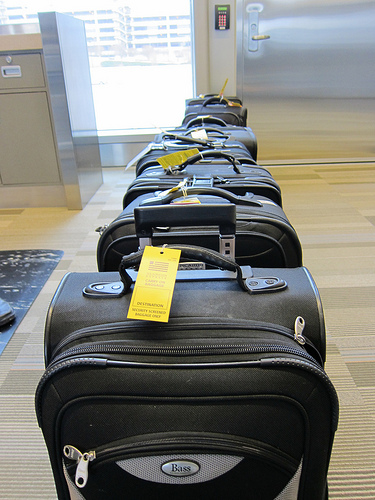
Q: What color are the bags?
A: Black and gray.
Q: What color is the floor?
A: Brown, gray and white.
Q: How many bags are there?
A: Seven.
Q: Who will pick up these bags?
A: Men or women.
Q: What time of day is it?
A: Daytime.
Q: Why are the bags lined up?
A: They are waiting to be put on the plane.